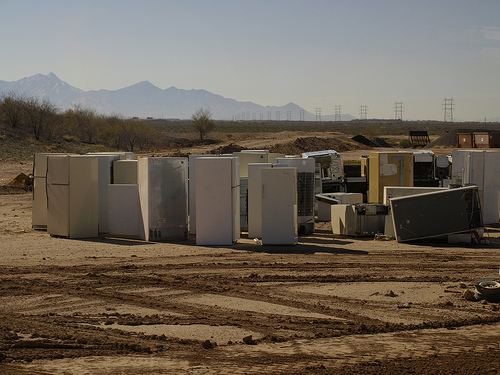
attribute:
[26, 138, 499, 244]
fridges — broken, old, obsolete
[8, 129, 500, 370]
junk yard — dirt covered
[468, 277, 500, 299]
wheel — old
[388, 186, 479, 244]
back — silver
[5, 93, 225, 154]
trees — green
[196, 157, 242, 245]
fridge — white, old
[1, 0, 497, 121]
sky — blue